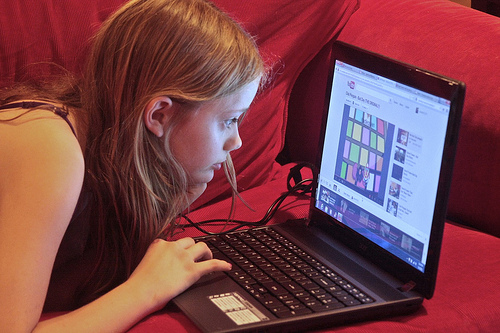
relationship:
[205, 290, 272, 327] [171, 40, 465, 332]
label on laptop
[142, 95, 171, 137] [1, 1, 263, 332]
right ear of girl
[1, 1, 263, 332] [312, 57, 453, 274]
girl looking at screen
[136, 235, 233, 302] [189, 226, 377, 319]
hand touching keyboard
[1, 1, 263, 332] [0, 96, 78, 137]
girl wears tank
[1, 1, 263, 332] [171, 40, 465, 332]
girl touching laptop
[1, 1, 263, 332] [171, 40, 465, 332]
girl looking at laptop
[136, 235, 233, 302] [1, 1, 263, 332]
hand of girl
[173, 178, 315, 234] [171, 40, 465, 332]
wires on laptop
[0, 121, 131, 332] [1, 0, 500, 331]
arms on couch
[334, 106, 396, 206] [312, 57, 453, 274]
image on screen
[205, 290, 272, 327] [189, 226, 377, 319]
label under keyboard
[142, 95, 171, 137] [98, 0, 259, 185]
right ear on head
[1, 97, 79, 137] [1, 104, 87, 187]
strap on shoulder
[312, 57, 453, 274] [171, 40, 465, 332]
screen of laptop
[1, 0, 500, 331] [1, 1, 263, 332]
couch under girl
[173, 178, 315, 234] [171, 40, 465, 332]
wires of laptop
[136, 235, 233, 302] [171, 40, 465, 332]
hand on laptop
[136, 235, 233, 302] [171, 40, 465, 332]
hand using laptop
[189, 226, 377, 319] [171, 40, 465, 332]
keyboard of laptop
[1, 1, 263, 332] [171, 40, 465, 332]
girl using laptop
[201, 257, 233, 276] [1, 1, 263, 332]
finger of girl